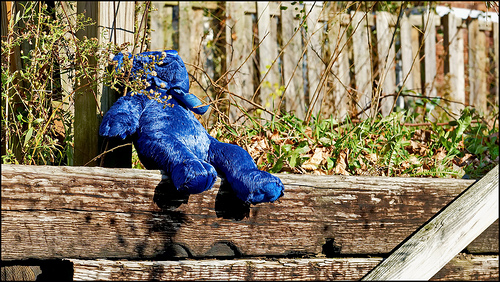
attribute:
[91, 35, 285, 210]
bear — blue, leaning, stuffed, sitting, shining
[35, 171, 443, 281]
wood — stacks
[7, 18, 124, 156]
plant — ggreen, green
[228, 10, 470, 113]
fence — wooden, behind, wood, grey, brown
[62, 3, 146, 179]
post — wooden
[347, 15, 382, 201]
beam — wooden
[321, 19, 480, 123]
railway — wooden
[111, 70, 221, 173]
elephant — blue, stuffed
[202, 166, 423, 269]
ledge — wood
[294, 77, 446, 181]
grass — wild, mixed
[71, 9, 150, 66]
stick — wooden